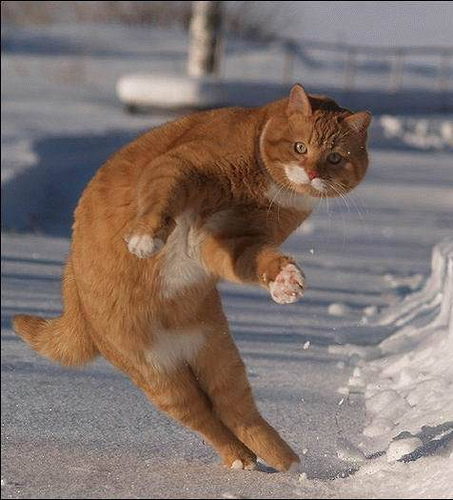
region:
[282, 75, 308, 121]
Right ear of cat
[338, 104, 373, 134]
Left ear of cat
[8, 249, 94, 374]
Long tail of cat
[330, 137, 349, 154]
Left eye of cat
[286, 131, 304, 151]
Right eye of cat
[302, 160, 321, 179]
Nose of cat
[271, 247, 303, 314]
Left paw of cat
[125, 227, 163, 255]
Right paw of cat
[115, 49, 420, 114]
White and black ship in background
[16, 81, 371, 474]
Tan and white cat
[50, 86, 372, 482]
Strange position cat finds self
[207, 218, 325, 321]
Claws out and at ready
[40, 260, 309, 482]
Incredible foot balancing act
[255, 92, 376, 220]
Facial expression intent dilemma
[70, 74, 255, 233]
Back arched right self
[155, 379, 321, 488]
Both feet clutch stability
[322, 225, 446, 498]
Dirty snow along street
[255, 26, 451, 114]
Hazy background possible bridge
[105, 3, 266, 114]
Unknown object behind cat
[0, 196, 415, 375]
Shadow lines from light left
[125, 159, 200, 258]
the leg of a cat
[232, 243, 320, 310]
the leg of a cat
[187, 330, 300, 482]
the leg of a cat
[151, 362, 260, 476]
the leg of a cat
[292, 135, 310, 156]
the eye of a cat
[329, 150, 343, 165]
the eye of a cat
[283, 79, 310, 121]
the ear of a cat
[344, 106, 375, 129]
the ear of a cat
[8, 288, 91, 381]
the tail of a cat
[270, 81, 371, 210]
the head of a cat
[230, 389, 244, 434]
back leg of a cat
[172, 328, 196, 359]
white patch of a cat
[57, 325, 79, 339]
tail of a cat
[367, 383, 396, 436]
white snowy surface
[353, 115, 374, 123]
ear of a cat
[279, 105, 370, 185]
head of a cat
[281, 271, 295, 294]
paws of a brown cat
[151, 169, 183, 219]
front leg of a cat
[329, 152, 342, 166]
eye of a cat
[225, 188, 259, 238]
body of a brown cat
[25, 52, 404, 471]
the cat on it's feet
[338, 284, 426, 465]
snow on the side of the scene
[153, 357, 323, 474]
the feet of the cat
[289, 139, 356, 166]
the nice cat eyes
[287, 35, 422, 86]
the fence in the background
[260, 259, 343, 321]
the paws of the cat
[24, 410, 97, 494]
snow on the ground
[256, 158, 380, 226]
the cat's mouth and whiskers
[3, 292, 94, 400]
the ca'ts nice tail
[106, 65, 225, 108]
a stool in the back